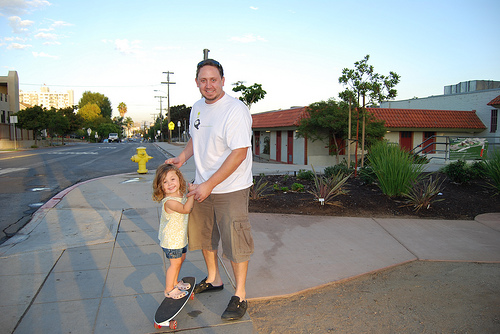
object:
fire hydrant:
[130, 147, 154, 175]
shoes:
[220, 292, 247, 322]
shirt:
[153, 192, 193, 247]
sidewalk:
[1, 148, 185, 332]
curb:
[68, 165, 178, 191]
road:
[0, 143, 181, 244]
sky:
[4, 4, 498, 118]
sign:
[167, 120, 176, 130]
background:
[4, 72, 496, 158]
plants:
[358, 135, 435, 198]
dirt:
[254, 175, 496, 218]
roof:
[350, 105, 493, 133]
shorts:
[188, 187, 256, 264]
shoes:
[163, 287, 191, 301]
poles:
[155, 95, 165, 142]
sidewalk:
[150, 130, 305, 184]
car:
[108, 133, 120, 143]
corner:
[162, 150, 193, 169]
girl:
[151, 163, 188, 301]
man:
[161, 57, 257, 321]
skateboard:
[151, 274, 199, 332]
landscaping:
[256, 145, 498, 219]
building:
[245, 105, 490, 168]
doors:
[421, 131, 439, 155]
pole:
[160, 71, 176, 144]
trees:
[9, 104, 53, 148]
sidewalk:
[3, 125, 78, 165]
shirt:
[187, 93, 254, 194]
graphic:
[193, 111, 202, 130]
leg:
[165, 257, 181, 297]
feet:
[163, 287, 189, 300]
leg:
[205, 248, 221, 282]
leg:
[232, 257, 246, 302]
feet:
[194, 276, 224, 294]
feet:
[219, 296, 248, 322]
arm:
[213, 109, 250, 205]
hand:
[185, 181, 212, 203]